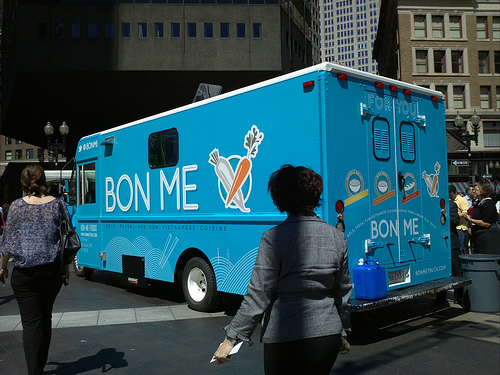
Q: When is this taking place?
A: Daytime.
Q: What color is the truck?
A: Blue.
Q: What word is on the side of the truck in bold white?
A: Bon me.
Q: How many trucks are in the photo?
A: One.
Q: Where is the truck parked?
A: Street.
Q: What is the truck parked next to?
A: Sidewalk.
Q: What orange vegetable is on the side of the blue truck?
A: Carrot.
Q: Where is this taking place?
A: City street.